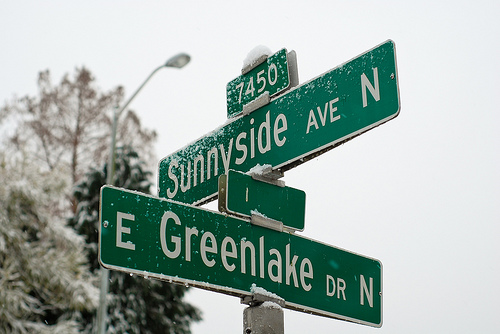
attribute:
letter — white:
[360, 272, 375, 309]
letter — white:
[151, 201, 190, 265]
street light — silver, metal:
[96, 50, 191, 332]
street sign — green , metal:
[218, 47, 293, 119]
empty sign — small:
[220, 167, 314, 233]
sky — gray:
[3, 2, 496, 332]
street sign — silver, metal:
[138, 37, 403, 229]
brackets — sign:
[253, 167, 289, 185]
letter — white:
[218, 232, 235, 275]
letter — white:
[183, 227, 203, 264]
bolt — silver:
[97, 216, 111, 231]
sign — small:
[203, 67, 319, 92]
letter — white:
[342, 58, 399, 140]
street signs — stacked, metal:
[125, 112, 397, 318]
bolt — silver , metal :
[101, 216, 113, 233]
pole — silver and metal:
[86, 284, 127, 329]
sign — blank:
[131, 47, 382, 179]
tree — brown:
[3, 74, 170, 332]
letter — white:
[162, 209, 182, 259]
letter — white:
[135, 199, 193, 274]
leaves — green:
[108, 283, 185, 324]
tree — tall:
[1, 57, 206, 332]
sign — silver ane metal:
[156, 37, 401, 206]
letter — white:
[356, 58, 382, 107]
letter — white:
[196, 83, 323, 194]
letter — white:
[162, 217, 297, 285]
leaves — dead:
[12, 61, 103, 138]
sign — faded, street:
[218, 163, 305, 231]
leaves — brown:
[2, 76, 147, 268]